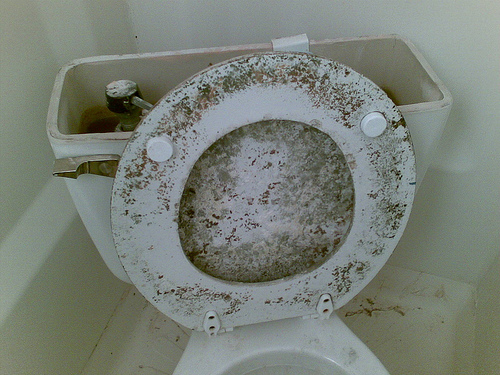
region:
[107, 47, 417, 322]
dirty toilet lid leaning against water tank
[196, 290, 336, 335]
two fasteners with two screws each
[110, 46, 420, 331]
brown dots forming ring on bottom of toilet seat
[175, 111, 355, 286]
brown and gray grime on bottom of toilet lid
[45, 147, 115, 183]
spots on silver lever on top corner of tank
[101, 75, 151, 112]
dust on black cap and rod of plumbing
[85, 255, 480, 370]
dirt, smears and stains on platform below toilet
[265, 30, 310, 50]
wire band on tank edge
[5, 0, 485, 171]
dark speck on bathroom wall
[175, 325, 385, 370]
dirt on edge of toilet-bowl rim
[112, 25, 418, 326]
a toilet with out a tank lid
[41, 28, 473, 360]
a toilet tank without lid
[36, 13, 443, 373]
a dirty bathroom toilet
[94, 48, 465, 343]
a dirty white toilet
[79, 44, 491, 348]
a bathroom toilet that is dirty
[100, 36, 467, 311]
a white bathroom toilet that is dirty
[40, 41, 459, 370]
a dirty toilet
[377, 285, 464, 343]
dirt on the floor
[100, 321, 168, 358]
white floor under the toilet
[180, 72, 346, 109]
dirt on the toilet seat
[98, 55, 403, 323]
a white toilet seat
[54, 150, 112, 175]
a handle on the toilet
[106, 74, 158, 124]
a black post in the toilet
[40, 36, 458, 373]
an old and dirty toilet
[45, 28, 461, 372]
White toilet in the room.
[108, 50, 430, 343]
Toilet lid on the toilet.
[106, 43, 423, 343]
Mold on the toilet seat.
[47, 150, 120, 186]
Silver colored flush handle.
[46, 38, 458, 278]
Back part of the toilet.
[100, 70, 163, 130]
Plumbing in the toilet back.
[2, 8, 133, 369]
White bathtub in the background.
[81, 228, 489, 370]
White floor on the ground.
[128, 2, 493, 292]
White wall in the background.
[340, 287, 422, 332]
Dirt on the floor.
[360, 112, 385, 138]
White cover on underside of toilet seat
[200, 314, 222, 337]
White hinge on toilet seat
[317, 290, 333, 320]
Hinge with two screws on toilet seat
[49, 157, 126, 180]
Metal flush handle on toilet seat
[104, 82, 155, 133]
Water pump inside toilet tank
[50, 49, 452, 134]
Toilet tank opening behind toilet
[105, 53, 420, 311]
Round toilet seat on toilet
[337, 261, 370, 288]
Dirt stains on toilet seat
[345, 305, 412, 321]
Stains on floor near toilet